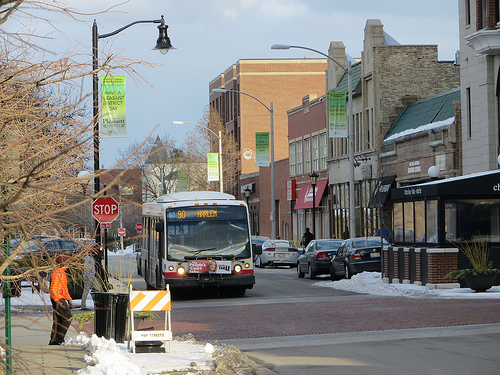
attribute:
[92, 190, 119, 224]
stop sign — white, red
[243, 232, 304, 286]
car — grey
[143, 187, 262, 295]
bus — white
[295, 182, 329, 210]
awning — red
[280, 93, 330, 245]
building — red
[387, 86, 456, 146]
roof — green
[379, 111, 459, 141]
snow — white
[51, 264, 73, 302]
jacket — orange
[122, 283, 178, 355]
barrier — yellow, white, for traffic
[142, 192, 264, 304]
bus — white, public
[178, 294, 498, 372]
street — red, gray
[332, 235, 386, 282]
car — black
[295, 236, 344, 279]
car — grey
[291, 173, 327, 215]
canopy — red, white